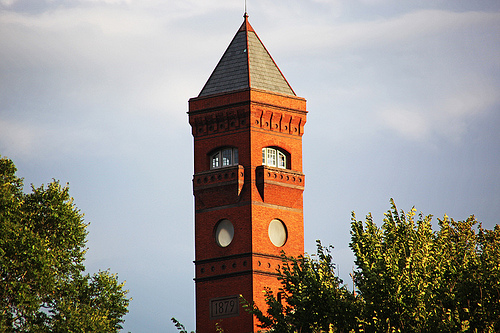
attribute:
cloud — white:
[9, 0, 488, 185]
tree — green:
[2, 157, 132, 331]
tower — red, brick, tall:
[188, 3, 310, 333]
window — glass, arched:
[207, 146, 240, 175]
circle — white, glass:
[267, 218, 289, 249]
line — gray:
[194, 202, 303, 215]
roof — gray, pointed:
[197, 17, 296, 98]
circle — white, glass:
[212, 217, 235, 246]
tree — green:
[241, 186, 499, 333]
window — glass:
[260, 145, 290, 170]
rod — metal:
[243, 0, 249, 18]